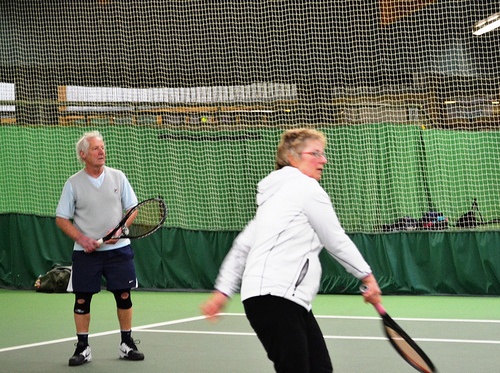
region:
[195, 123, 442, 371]
woman holding a tennis racket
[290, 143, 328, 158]
glases over a woman's eyes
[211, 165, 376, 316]
white jacket on a woman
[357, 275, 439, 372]
tennis racket in a woman's hand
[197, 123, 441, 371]
woman playing tennis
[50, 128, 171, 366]
man holding a tennis racket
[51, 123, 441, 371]
man and woman holding tennis rackets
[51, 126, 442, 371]
man and woman playing tennis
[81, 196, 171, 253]
black tennis racket in a man's hand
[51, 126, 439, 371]
two elderly people playing tennis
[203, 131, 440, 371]
a woman wearing a white jacket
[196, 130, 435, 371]
a man wearing a sweater vest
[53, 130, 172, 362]
a man wearing knee braces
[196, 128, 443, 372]
a woman swinging a tennis racket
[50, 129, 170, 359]
a man with a tennis racket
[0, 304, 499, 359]
white lines on a tennis court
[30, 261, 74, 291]
a dufflebag on the ground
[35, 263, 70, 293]
a green dufflebag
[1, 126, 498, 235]
a white net hanging from the wall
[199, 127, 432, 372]
woman wearing black plants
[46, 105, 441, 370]
two old people playing tennis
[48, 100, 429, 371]
a male and a female playing tennis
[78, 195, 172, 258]
a black and white tennis racket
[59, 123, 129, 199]
man has gray hair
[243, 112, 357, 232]
woman has gray hair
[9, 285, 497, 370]
tennis court is green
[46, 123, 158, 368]
white lines on the floor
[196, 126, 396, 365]
woman wears white jacket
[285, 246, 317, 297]
a pocket in a jacket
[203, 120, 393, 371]
woman wears black pants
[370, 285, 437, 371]
a large black tennis racket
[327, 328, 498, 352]
a long white line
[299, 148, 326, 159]
a woman's eyeglasses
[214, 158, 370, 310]
a woman's white jacket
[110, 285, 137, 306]
a black knee pad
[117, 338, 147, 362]
a man's black and white tennis shoe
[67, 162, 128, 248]
a man's gray sweater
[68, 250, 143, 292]
a man's blue and white shorts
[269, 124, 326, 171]
a woman's short cut hair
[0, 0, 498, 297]
a large green net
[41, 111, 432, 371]
A man and a woman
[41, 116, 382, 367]
People are playing tennis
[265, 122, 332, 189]
A side view of a woman's head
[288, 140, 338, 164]
Woman is wearing eyeglasses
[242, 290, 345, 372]
Woman is wearing black pants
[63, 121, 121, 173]
Man has gray hair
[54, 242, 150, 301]
Man is wearing shorts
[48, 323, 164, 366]
Man is wearing tennis shoes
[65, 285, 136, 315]
Man is wearing kneepads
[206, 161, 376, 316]
Woman is wearing a white hoodie